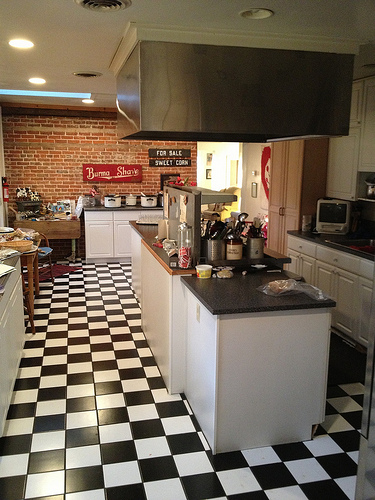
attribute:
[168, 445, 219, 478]
tile — white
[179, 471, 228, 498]
tile — black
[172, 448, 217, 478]
tile — white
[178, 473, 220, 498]
tile — black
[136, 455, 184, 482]
tile — black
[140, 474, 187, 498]
tile — white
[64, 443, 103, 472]
tile — white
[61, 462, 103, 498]
tile — black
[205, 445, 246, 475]
tile — black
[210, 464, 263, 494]
tile — white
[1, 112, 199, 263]
wall — bricked, brick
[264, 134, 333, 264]
cupboard — brown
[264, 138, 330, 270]
cupboard — wooden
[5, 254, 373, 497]
floor — black, white, checkered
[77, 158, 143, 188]
sign — red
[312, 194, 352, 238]
tv — white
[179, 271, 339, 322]
countertops — dark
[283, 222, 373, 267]
countertops — dark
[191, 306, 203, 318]
outlet — electric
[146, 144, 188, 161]
sign — for sale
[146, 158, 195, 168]
sign — sweet corn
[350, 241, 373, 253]
cloth — red, dish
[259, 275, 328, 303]
bag — plastic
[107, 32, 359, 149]
vent — large, kitchen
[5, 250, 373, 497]
tiles — black, white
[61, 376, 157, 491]
tiles — black and white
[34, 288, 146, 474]
floor — Checkered, tile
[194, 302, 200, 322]
receptacle — electrical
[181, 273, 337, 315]
countertop — granite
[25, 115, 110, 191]
wall — brick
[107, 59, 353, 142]
duct — exhaust fan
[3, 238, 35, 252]
basket — wicker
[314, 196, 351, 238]
tv — small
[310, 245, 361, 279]
drawer — cabinet